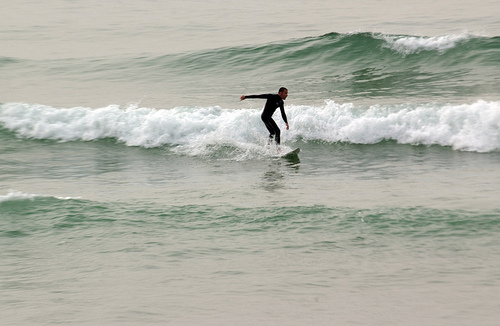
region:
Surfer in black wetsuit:
[241, 82, 296, 139]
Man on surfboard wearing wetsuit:
[236, 82, 309, 160]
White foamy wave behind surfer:
[151, 101, 371, 144]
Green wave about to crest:
[221, 18, 472, 68]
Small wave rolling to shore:
[19, 179, 145, 223]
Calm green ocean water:
[166, 259, 334, 314]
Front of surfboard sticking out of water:
[278, 140, 314, 164]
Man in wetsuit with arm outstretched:
[231, 87, 296, 104]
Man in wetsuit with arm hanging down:
[271, 82, 296, 129]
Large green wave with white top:
[357, 25, 481, 74]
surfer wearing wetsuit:
[240, 86, 290, 147]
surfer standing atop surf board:
[236, 85, 299, 160]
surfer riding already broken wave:
[218, 83, 326, 165]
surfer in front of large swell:
[228, 25, 420, 163]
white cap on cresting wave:
[368, 28, 473, 60]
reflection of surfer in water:
[258, 147, 300, 199]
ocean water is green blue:
[121, 180, 435, 299]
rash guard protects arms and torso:
[238, 93, 289, 121]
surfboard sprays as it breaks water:
[245, 142, 304, 161]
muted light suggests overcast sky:
[8, 7, 487, 317]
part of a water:
[256, 243, 310, 306]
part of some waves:
[306, 195, 381, 290]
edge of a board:
[278, 135, 300, 162]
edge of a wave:
[246, 197, 320, 279]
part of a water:
[265, 255, 304, 296]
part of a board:
[264, 124, 291, 171]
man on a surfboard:
[226, 79, 318, 185]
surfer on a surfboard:
[234, 71, 323, 163]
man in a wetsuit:
[238, 81, 303, 171]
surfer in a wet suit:
[228, 79, 306, 174]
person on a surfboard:
[232, 77, 302, 164]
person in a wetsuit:
[230, 77, 319, 169]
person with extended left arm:
[216, 73, 306, 190]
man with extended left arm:
[226, 80, 305, 190]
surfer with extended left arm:
[238, 69, 318, 162]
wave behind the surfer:
[284, 21, 499, 83]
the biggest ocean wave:
[128, 22, 498, 72]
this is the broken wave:
[3, 95, 498, 171]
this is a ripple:
[11, 177, 474, 277]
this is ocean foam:
[3, 90, 499, 167]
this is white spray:
[365, 25, 497, 57]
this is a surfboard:
[246, 128, 308, 171]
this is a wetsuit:
[241, 84, 296, 152]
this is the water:
[1, 0, 499, 317]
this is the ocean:
[1, 2, 490, 324]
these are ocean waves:
[21, 37, 466, 234]